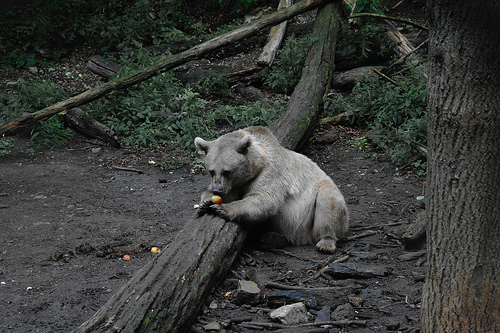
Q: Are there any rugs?
A: No, there are no rugs.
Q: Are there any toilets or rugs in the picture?
A: No, there are no rugs or toilets.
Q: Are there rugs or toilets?
A: No, there are no rugs or toilets.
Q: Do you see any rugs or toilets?
A: No, there are no rugs or toilets.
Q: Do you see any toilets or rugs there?
A: No, there are no rugs or toilets.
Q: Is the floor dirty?
A: Yes, the floor is dirty.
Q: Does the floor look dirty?
A: Yes, the floor is dirty.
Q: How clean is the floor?
A: The floor is dirty.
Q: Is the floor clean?
A: No, the floor is dirty.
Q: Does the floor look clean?
A: No, the floor is dirty.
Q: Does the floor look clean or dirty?
A: The floor is dirty.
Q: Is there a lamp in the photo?
A: No, there are no lamps.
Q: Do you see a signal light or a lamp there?
A: No, there are no lamps or traffic lights.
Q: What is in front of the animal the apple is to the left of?
A: The log is in front of the bear.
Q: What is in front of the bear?
A: The log is in front of the bear.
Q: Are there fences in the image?
A: No, there are no fences.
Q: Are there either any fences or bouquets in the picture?
A: No, there are no fences or bouquets.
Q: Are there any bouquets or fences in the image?
A: No, there are no fences or bouquets.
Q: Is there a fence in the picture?
A: No, there are no fences.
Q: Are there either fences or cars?
A: No, there are no fences or cars.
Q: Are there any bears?
A: Yes, there is a bear.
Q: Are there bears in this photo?
A: Yes, there is a bear.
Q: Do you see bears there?
A: Yes, there is a bear.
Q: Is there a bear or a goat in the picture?
A: Yes, there is a bear.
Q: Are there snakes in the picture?
A: No, there are no snakes.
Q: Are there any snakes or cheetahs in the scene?
A: No, there are no snakes or cheetahs.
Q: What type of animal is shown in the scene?
A: The animal is a bear.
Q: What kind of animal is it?
A: The animal is a bear.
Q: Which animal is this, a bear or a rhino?
A: That is a bear.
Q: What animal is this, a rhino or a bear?
A: That is a bear.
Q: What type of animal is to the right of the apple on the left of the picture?
A: The animal is a bear.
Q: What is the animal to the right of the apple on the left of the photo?
A: The animal is a bear.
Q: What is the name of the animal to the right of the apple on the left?
A: The animal is a bear.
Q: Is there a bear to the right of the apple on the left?
A: Yes, there is a bear to the right of the apple.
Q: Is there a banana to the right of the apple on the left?
A: No, there is a bear to the right of the apple.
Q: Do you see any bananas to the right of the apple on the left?
A: No, there is a bear to the right of the apple.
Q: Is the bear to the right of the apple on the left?
A: Yes, the bear is to the right of the apple.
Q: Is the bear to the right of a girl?
A: No, the bear is to the right of the apple.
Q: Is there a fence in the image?
A: No, there are no fences.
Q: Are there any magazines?
A: No, there are no magazines.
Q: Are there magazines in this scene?
A: No, there are no magazines.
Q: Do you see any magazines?
A: No, there are no magazines.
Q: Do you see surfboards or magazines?
A: No, there are no magazines or surfboards.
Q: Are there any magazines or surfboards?
A: No, there are no magazines or surfboards.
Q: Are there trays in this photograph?
A: No, there are no trays.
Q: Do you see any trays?
A: No, there are no trays.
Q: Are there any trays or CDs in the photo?
A: No, there are no trays or cds.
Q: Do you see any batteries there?
A: No, there are no batteries.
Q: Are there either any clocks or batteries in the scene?
A: No, there are no batteries or clocks.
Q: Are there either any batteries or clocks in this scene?
A: No, there are no batteries or clocks.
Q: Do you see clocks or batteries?
A: No, there are no batteries or clocks.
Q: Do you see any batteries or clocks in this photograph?
A: No, there are no batteries or clocks.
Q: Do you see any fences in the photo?
A: No, there are no fences.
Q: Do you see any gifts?
A: No, there are no gifts.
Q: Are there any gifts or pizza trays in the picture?
A: No, there are no gifts or pizza trays.